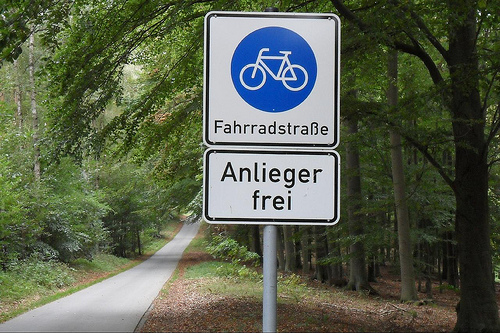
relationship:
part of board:
[209, 29, 234, 47] [205, 6, 350, 146]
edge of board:
[194, 5, 215, 11] [205, 6, 350, 146]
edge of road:
[163, 261, 191, 275] [67, 212, 201, 332]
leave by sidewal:
[201, 290, 226, 304] [142, 233, 214, 330]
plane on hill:
[27, 193, 83, 259] [29, 165, 162, 274]